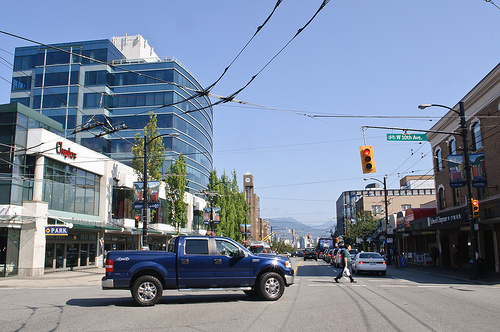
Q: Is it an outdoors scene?
A: Yes, it is outdoors.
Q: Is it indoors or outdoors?
A: It is outdoors.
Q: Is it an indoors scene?
A: No, it is outdoors.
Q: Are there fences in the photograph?
A: No, there are no fences.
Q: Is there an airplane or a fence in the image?
A: No, there are no fences or airplanes.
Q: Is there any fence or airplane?
A: No, there are no fences or airplanes.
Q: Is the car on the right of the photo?
A: Yes, the car is on the right of the image.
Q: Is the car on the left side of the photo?
A: No, the car is on the right of the image.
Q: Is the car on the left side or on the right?
A: The car is on the right of the image.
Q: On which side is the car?
A: The car is on the right of the image.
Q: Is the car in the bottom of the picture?
A: Yes, the car is in the bottom of the image.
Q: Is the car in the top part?
A: No, the car is in the bottom of the image.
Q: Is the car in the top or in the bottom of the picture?
A: The car is in the bottom of the image.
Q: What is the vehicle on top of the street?
A: The vehicle is a car.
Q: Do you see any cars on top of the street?
A: Yes, there is a car on top of the street.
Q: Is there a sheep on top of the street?
A: No, there is a car on top of the street.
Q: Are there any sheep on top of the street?
A: No, there is a car on top of the street.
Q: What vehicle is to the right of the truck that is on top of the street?
A: The vehicle is a car.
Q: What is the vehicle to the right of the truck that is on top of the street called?
A: The vehicle is a car.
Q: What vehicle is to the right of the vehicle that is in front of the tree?
A: The vehicle is a car.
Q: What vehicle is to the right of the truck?
A: The vehicle is a car.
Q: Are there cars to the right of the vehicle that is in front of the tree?
A: Yes, there is a car to the right of the truck.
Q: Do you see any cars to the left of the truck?
A: No, the car is to the right of the truck.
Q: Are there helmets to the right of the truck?
A: No, there is a car to the right of the truck.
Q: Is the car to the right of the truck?
A: Yes, the car is to the right of the truck.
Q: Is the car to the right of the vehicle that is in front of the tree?
A: Yes, the car is to the right of the truck.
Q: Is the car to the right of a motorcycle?
A: No, the car is to the right of the truck.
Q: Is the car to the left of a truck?
A: No, the car is to the right of a truck.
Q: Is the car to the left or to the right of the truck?
A: The car is to the right of the truck.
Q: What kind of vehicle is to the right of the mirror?
A: The vehicle is a car.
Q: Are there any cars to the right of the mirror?
A: Yes, there is a car to the right of the mirror.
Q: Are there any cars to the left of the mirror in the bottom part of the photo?
A: No, the car is to the right of the mirror.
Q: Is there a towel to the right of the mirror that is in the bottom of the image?
A: No, there is a car to the right of the mirror.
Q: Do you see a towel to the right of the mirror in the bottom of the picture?
A: No, there is a car to the right of the mirror.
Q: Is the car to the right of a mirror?
A: Yes, the car is to the right of a mirror.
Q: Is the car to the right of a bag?
A: No, the car is to the right of a mirror.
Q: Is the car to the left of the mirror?
A: No, the car is to the right of the mirror.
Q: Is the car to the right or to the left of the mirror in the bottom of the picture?
A: The car is to the right of the mirror.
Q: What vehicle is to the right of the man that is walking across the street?
A: The vehicle is a car.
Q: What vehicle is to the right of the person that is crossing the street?
A: The vehicle is a car.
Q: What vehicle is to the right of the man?
A: The vehicle is a car.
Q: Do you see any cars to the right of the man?
A: Yes, there is a car to the right of the man.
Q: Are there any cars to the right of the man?
A: Yes, there is a car to the right of the man.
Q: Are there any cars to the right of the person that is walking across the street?
A: Yes, there is a car to the right of the man.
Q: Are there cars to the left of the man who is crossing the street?
A: No, the car is to the right of the man.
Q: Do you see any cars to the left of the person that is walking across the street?
A: No, the car is to the right of the man.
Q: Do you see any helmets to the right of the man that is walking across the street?
A: No, there is a car to the right of the man.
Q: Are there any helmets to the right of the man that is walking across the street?
A: No, there is a car to the right of the man.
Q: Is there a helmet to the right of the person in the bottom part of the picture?
A: No, there is a car to the right of the man.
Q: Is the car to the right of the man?
A: Yes, the car is to the right of the man.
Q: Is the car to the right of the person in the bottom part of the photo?
A: Yes, the car is to the right of the man.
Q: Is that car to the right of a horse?
A: No, the car is to the right of the man.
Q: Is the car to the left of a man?
A: No, the car is to the right of a man.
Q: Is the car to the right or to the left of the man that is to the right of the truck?
A: The car is to the right of the man.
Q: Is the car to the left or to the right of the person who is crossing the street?
A: The car is to the right of the man.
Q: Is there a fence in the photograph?
A: No, there are no fences.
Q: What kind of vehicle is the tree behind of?
A: The tree is behind the truck.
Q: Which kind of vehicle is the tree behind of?
A: The tree is behind the truck.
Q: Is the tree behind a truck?
A: Yes, the tree is behind a truck.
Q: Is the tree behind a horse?
A: No, the tree is behind a truck.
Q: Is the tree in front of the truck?
A: No, the tree is behind the truck.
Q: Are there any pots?
A: No, there are no pots.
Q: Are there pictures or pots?
A: No, there are no pots or pictures.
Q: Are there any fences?
A: No, there are no fences.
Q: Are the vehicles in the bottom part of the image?
A: Yes, the vehicles are in the bottom of the image.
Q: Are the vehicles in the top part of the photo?
A: No, the vehicles are in the bottom of the image.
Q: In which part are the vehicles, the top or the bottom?
A: The vehicles are in the bottom of the image.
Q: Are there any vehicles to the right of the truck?
A: Yes, there are vehicles to the right of the truck.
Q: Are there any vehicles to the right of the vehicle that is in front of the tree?
A: Yes, there are vehicles to the right of the truck.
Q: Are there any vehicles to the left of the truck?
A: No, the vehicles are to the right of the truck.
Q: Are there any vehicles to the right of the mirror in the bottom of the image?
A: Yes, there are vehicles to the right of the mirror.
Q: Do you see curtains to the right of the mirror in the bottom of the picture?
A: No, there are vehicles to the right of the mirror.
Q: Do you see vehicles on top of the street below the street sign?
A: Yes, there are vehicles on top of the street.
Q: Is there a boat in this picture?
A: No, there are no boats.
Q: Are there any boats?
A: No, there are no boats.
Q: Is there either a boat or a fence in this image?
A: No, there are no boats or fences.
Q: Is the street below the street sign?
A: Yes, the street is below the street sign.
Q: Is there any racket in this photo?
A: No, there are no rackets.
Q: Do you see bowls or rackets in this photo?
A: No, there are no rackets or bowls.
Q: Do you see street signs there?
A: Yes, there is a street sign.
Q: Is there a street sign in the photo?
A: Yes, there is a street sign.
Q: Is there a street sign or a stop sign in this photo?
A: Yes, there is a street sign.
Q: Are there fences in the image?
A: No, there are no fences.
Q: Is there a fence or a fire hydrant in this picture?
A: No, there are no fences or fire hydrants.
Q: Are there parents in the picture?
A: No, there are no parents.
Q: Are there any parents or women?
A: No, there are no parents or women.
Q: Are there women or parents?
A: No, there are no parents or women.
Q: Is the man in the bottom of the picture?
A: Yes, the man is in the bottom of the image.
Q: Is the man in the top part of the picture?
A: No, the man is in the bottom of the image.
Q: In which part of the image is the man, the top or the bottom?
A: The man is in the bottom of the image.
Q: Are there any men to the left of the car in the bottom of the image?
A: Yes, there is a man to the left of the car.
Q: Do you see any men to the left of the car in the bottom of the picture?
A: Yes, there is a man to the left of the car.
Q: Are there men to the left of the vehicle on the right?
A: Yes, there is a man to the left of the car.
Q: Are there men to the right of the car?
A: No, the man is to the left of the car.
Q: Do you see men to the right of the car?
A: No, the man is to the left of the car.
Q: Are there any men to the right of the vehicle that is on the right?
A: No, the man is to the left of the car.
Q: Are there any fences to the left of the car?
A: No, there is a man to the left of the car.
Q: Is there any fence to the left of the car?
A: No, there is a man to the left of the car.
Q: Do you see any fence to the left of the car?
A: No, there is a man to the left of the car.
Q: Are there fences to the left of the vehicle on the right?
A: No, there is a man to the left of the car.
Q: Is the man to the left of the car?
A: Yes, the man is to the left of the car.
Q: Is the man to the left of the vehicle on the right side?
A: Yes, the man is to the left of the car.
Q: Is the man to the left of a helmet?
A: No, the man is to the left of the car.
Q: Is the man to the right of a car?
A: No, the man is to the left of a car.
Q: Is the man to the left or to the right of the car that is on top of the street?
A: The man is to the left of the car.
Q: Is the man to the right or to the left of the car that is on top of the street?
A: The man is to the left of the car.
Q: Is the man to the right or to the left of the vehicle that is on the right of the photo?
A: The man is to the left of the car.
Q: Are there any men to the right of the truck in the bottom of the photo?
A: Yes, there is a man to the right of the truck.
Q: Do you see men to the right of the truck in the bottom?
A: Yes, there is a man to the right of the truck.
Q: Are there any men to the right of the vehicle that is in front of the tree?
A: Yes, there is a man to the right of the truck.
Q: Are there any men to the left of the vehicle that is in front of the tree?
A: No, the man is to the right of the truck.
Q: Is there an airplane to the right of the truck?
A: No, there is a man to the right of the truck.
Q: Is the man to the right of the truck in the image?
A: Yes, the man is to the right of the truck.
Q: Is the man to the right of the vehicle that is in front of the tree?
A: Yes, the man is to the right of the truck.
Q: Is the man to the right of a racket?
A: No, the man is to the right of the truck.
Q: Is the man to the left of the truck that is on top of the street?
A: No, the man is to the right of the truck.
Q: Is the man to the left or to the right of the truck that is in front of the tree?
A: The man is to the right of the truck.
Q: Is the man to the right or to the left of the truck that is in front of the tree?
A: The man is to the right of the truck.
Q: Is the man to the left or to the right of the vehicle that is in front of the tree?
A: The man is to the right of the truck.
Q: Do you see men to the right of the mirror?
A: Yes, there is a man to the right of the mirror.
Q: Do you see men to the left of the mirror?
A: No, the man is to the right of the mirror.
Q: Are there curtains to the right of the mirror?
A: No, there is a man to the right of the mirror.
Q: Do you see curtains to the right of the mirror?
A: No, there is a man to the right of the mirror.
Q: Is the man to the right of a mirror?
A: Yes, the man is to the right of a mirror.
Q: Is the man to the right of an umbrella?
A: No, the man is to the right of a mirror.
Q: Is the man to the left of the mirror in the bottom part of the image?
A: No, the man is to the right of the mirror.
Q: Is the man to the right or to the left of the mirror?
A: The man is to the right of the mirror.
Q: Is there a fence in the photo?
A: No, there are no fences.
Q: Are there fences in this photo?
A: No, there are no fences.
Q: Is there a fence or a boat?
A: No, there are no fences or boats.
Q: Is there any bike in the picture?
A: No, there are no bikes.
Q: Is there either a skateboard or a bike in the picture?
A: No, there are no bikes or skateboards.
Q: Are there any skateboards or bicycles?
A: No, there are no bicycles or skateboards.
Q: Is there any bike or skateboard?
A: No, there are no bikes or skateboards.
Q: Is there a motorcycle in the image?
A: No, there are no motorcycles.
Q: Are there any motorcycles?
A: No, there are no motorcycles.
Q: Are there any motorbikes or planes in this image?
A: No, there are no motorbikes or planes.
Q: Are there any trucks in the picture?
A: Yes, there is a truck.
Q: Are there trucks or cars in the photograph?
A: Yes, there is a truck.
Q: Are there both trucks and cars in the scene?
A: Yes, there are both a truck and a car.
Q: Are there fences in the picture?
A: No, there are no fences.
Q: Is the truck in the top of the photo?
A: No, the truck is in the bottom of the image.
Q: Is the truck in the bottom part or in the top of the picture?
A: The truck is in the bottom of the image.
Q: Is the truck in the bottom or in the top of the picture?
A: The truck is in the bottom of the image.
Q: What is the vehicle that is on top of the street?
A: The vehicle is a truck.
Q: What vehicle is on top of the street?
A: The vehicle is a truck.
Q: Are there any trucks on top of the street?
A: Yes, there is a truck on top of the street.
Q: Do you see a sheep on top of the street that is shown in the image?
A: No, there is a truck on top of the street.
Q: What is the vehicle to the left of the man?
A: The vehicle is a truck.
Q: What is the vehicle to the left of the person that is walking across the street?
A: The vehicle is a truck.